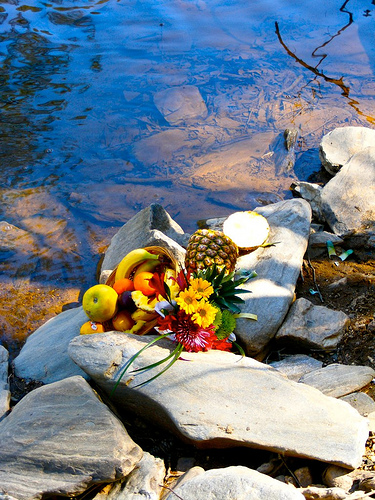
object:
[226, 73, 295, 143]
sticks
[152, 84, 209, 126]
rock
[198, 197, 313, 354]
rock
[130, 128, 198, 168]
rock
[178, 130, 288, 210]
rock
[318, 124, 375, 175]
rock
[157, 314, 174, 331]
flowers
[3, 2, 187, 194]
ripple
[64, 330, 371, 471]
rocks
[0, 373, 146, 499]
rocks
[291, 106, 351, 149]
rocks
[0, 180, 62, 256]
rocks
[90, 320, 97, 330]
sticker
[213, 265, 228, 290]
fronds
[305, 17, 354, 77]
reflection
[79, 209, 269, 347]
fruit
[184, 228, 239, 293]
pineapple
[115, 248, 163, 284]
banana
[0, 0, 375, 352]
water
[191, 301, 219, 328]
flower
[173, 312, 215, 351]
flower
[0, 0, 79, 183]
tree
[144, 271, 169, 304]
flowers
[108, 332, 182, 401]
foliage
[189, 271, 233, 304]
bouqet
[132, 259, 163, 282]
banana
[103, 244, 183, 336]
basket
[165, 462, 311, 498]
rock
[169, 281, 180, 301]
sun flowers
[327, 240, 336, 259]
debris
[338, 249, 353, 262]
debris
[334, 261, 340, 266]
debris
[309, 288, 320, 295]
debris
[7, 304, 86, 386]
rock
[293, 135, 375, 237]
rock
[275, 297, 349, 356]
rock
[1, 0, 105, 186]
reflection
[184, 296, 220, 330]
flower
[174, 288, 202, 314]
flower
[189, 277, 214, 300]
flower